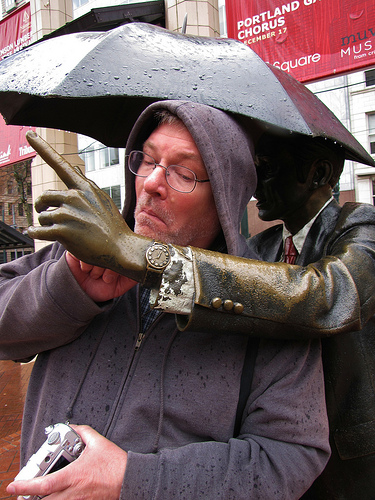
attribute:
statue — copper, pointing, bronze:
[19, 110, 373, 410]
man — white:
[13, 91, 328, 497]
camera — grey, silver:
[1, 432, 80, 498]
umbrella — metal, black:
[28, 12, 358, 193]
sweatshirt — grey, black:
[38, 241, 336, 497]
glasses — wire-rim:
[125, 153, 235, 186]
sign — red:
[231, 4, 372, 90]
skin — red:
[180, 181, 224, 247]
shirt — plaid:
[132, 293, 169, 339]